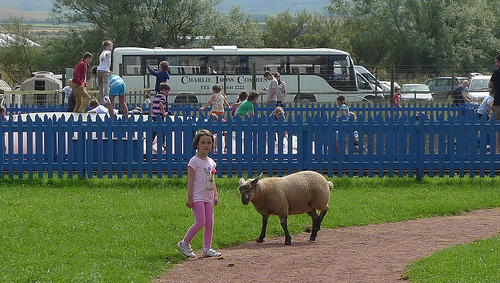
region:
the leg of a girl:
[203, 200, 215, 247]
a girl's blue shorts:
[107, 83, 129, 96]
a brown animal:
[230, 167, 331, 244]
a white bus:
[105, 45, 355, 100]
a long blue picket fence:
[0, 110, 495, 177]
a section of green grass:
[400, 230, 495, 280]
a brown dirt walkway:
[160, 205, 495, 280]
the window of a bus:
[334, 57, 353, 80]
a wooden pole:
[386, 60, 396, 100]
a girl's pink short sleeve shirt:
[187, 154, 219, 204]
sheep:
[237, 166, 335, 248]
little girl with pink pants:
[176, 126, 221, 260]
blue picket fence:
[2, 102, 498, 180]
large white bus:
[110, 40, 395, 112]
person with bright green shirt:
[232, 87, 262, 122]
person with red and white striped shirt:
[147, 82, 172, 128]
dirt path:
[160, 209, 499, 281]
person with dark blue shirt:
[148, 59, 173, 96]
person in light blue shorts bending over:
[105, 69, 127, 117]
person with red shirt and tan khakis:
[69, 49, 94, 113]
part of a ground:
[343, 242, 360, 264]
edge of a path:
[381, 200, 398, 216]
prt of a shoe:
[196, 235, 219, 266]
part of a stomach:
[277, 174, 315, 209]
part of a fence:
[297, 122, 364, 184]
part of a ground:
[334, 231, 369, 274]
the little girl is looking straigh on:
[177, 131, 222, 256]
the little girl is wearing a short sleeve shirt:
[187, 154, 219, 206]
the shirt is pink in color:
[187, 155, 218, 207]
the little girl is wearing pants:
[185, 200, 218, 246]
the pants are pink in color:
[180, 200, 212, 245]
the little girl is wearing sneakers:
[176, 238, 219, 258]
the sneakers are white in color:
[175, 237, 221, 259]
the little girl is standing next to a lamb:
[172, 125, 333, 260]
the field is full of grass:
[3, 160, 493, 280]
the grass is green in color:
[0, 167, 495, 279]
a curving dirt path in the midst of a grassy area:
[0, 176, 495, 281]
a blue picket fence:
[1, 110, 497, 178]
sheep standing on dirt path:
[231, 158, 371, 280]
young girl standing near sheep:
[169, 121, 333, 262]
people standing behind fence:
[93, 57, 359, 179]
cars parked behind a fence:
[354, 55, 498, 100]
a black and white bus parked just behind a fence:
[109, 43, 360, 103]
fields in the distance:
[0, 15, 106, 50]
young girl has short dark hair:
[188, 124, 216, 159]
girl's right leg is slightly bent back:
[172, 127, 227, 264]